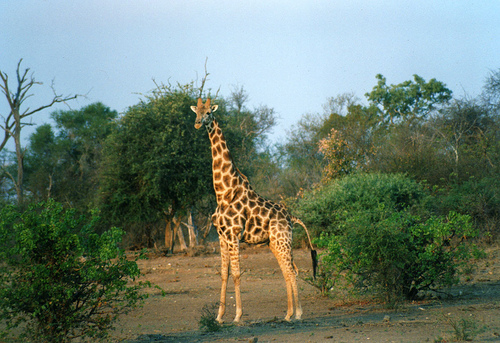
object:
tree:
[0, 57, 94, 213]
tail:
[292, 215, 319, 279]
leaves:
[100, 246, 113, 258]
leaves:
[132, 120, 164, 144]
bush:
[0, 198, 168, 342]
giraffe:
[189, 98, 318, 325]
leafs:
[389, 218, 400, 229]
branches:
[25, 107, 45, 116]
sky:
[0, 2, 500, 61]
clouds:
[249, 10, 319, 30]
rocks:
[324, 335, 334, 338]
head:
[190, 98, 219, 130]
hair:
[311, 249, 318, 280]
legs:
[268, 243, 294, 310]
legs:
[218, 236, 229, 314]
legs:
[224, 234, 242, 311]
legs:
[269, 221, 301, 309]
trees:
[16, 102, 120, 207]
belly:
[241, 219, 269, 244]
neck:
[205, 125, 253, 190]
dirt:
[0, 320, 499, 342]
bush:
[282, 169, 494, 307]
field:
[2, 235, 498, 341]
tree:
[92, 54, 285, 253]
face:
[194, 104, 212, 129]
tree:
[364, 73, 453, 127]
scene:
[0, 0, 499, 342]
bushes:
[0, 55, 500, 250]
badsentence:
[329, 300, 369, 311]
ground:
[164, 258, 208, 282]